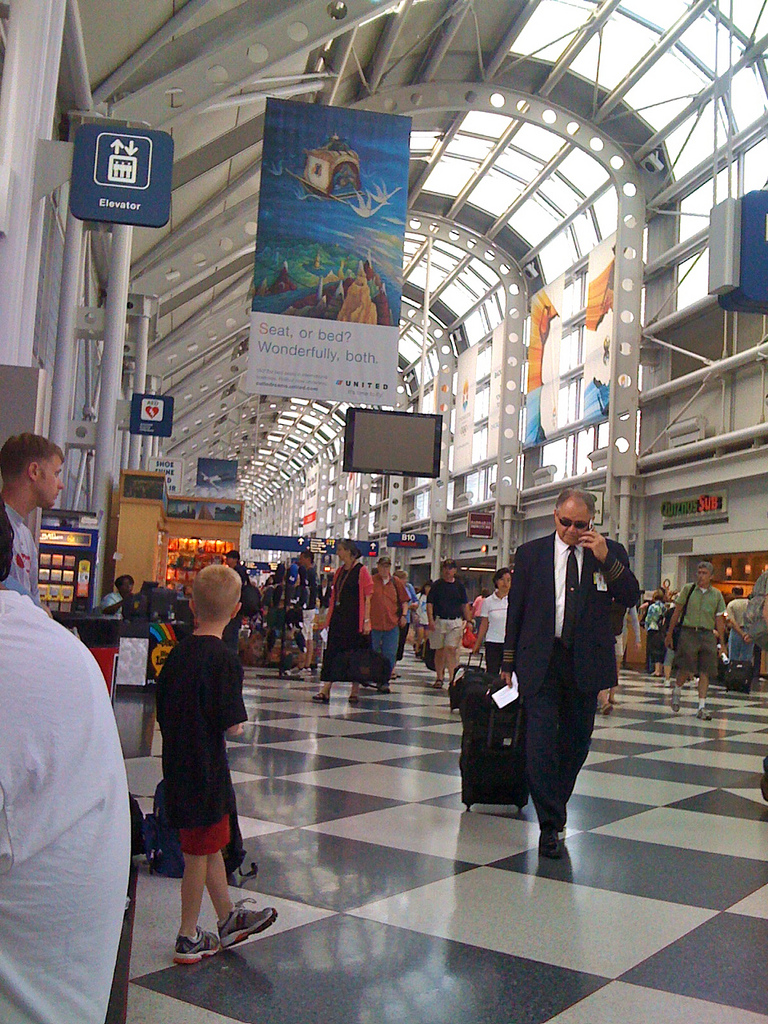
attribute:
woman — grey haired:
[312, 536, 384, 716]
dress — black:
[307, 557, 367, 684]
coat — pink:
[317, 561, 370, 633]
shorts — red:
[171, 808, 242, 863]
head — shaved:
[186, 558, 250, 648]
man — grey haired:
[663, 554, 735, 725]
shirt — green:
[676, 575, 726, 636]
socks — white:
[697, 695, 713, 715]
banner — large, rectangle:
[245, 96, 413, 414]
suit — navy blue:
[506, 531, 644, 836]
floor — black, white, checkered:
[98, 624, 765, 1021]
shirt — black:
[157, 633, 250, 824]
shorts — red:
[169, 814, 236, 867]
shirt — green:
[685, 590, 711, 624]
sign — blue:
[61, 115, 181, 230]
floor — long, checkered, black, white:
[131, 657, 741, 1021]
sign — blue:
[128, 386, 181, 446]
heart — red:
[142, 404, 161, 420]